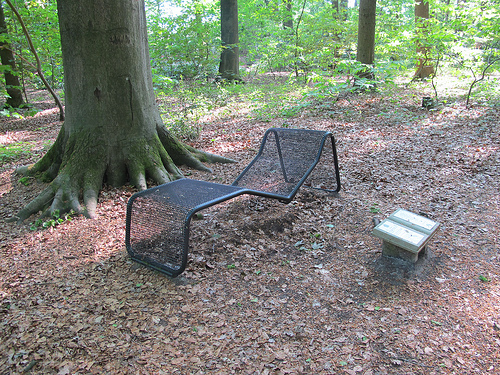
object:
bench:
[125, 126, 343, 277]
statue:
[372, 207, 442, 263]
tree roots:
[5, 125, 240, 222]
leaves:
[133, 283, 147, 288]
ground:
[0, 79, 500, 375]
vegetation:
[302, 59, 384, 104]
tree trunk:
[56, 0, 165, 125]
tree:
[351, 0, 382, 88]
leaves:
[326, 18, 334, 25]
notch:
[93, 87, 100, 98]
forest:
[0, 0, 499, 375]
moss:
[33, 120, 200, 192]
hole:
[94, 87, 102, 102]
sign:
[422, 97, 438, 112]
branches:
[294, 0, 306, 78]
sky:
[143, 0, 357, 33]